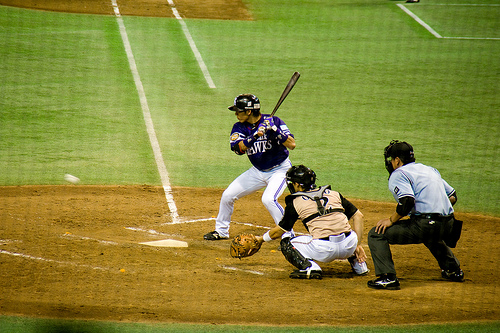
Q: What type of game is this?
A: Baseball.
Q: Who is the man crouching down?
A: The catcher.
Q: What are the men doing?
A: Playing baseball.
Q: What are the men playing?
A: Baseball.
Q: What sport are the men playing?
A: Baseball.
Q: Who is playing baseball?
A: The men.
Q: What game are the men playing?
A: Baseball.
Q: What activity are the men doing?
A: Playing baseball.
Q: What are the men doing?
A: Playing baseball.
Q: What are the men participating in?
A: Baseball.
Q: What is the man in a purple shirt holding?
A: A bat.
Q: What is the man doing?
A: Trying to hit a baseball.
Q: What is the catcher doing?
A: Moving his glove toward the ball.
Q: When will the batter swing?
A: In a fraction of a second.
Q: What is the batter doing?
A: Leaning back to get more power.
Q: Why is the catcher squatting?
A: Most pitches are aimed low.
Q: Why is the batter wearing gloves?
A: To protect his hand from impact.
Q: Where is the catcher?
A: Behind the plate.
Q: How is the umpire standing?
A: Crouched.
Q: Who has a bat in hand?
A: Batter.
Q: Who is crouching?
A: Player.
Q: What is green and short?
A: Grass.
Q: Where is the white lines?
A: Along the field.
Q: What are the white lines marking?
A: Baselines.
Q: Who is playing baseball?
A: The men.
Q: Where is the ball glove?
A: In the catcher's hand.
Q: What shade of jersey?
A: Purple.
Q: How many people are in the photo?
A: Three.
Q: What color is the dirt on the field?
A: Brown.